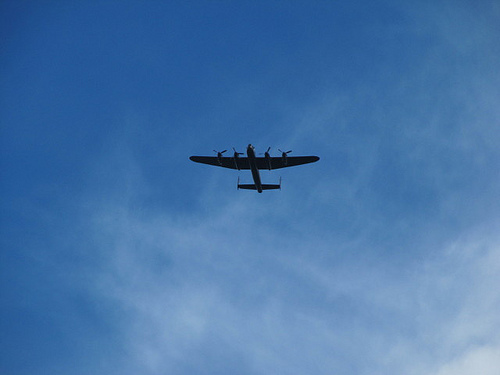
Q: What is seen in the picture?
A: Aeroplane.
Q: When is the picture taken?
A: Daytime.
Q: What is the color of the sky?
A: Blue.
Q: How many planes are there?
A: One.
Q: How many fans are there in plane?
A: 4.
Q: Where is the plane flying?
A: In the sky.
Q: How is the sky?
A: With some clouds.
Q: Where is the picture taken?
A: From the ground.